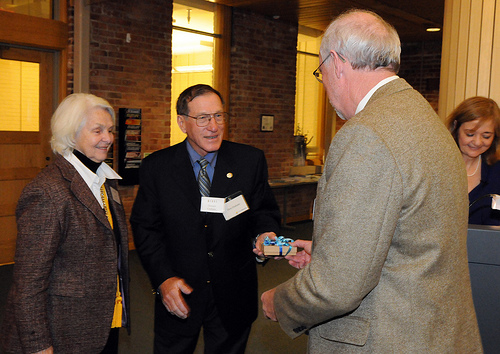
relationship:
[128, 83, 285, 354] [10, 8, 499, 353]
person at a gathering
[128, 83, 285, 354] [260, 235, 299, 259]
person giving gift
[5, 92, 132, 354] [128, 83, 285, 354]
woman standing next to person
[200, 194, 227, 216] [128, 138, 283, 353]
tag hanging on suit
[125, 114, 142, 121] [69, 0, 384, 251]
pamphlet hanging on wall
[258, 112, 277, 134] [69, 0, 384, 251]
plaque hanging on wall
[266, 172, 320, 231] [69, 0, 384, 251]
table leaning against wall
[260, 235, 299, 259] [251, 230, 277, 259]
gift held in hand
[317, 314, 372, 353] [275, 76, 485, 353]
pocket on side of jacket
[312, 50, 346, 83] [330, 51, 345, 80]
glasses worn on ear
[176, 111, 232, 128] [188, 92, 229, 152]
glasses worn on face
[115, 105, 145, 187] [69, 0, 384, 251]
magazine holder hanging on wall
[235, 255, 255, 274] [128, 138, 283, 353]
pocket cover of suit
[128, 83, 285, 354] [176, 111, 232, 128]
person wearing glasses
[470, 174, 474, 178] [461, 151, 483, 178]
pearl of a necklace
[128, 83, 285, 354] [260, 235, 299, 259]
person exchanging gift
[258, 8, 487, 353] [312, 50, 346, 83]
man wearing glasses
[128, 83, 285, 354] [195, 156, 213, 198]
person wearing a tie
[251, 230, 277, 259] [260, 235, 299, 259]
hand holding gift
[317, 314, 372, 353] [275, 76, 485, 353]
pocket on side of a jacket